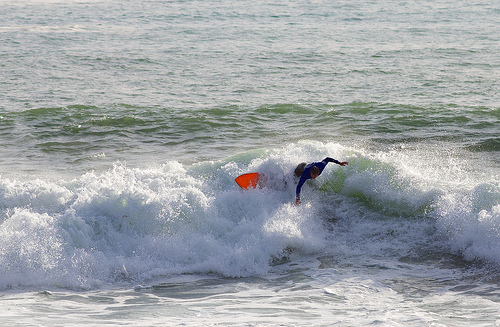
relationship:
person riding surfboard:
[285, 158, 352, 209] [231, 170, 262, 192]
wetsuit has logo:
[292, 157, 341, 199] [304, 162, 315, 169]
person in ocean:
[285, 158, 352, 209] [0, 1, 499, 326]